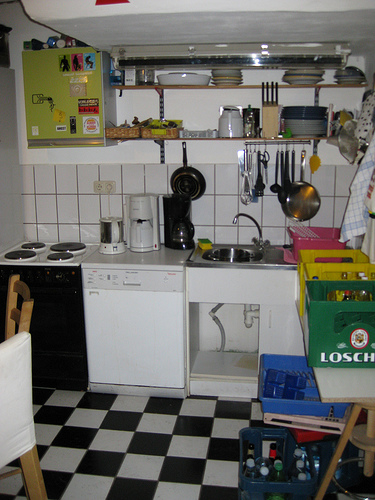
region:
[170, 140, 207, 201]
a black metal frying pan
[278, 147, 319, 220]
a silver metal pot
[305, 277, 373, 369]
a green plastic crate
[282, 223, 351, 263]
a pink dish rack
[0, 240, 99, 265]
a four burner stove top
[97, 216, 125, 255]
a white coffee pot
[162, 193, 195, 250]
a black coffee pot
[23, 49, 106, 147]
a green cabinet door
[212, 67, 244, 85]
a stack of bowls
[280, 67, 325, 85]
a stack of plates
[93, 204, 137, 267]
a coffee pot on the counter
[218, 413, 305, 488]
bottles in a crate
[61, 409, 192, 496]
a checker pattern on the floor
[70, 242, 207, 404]
a dishwasher in the kitchen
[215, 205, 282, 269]
a sink in the kitchen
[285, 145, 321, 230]
a pan hanging over a sink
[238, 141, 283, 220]
utensils hanging over a sink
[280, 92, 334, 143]
plates on the shelf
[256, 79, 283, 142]
a knife set on the shelf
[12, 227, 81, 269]
top of a stove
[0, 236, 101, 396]
A small black stove and oven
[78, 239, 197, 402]
A white dishwasher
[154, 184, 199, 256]
A black coffee maker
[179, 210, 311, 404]
A small kitchen sink and cabinet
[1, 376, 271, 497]
A black and white kitchen tile floor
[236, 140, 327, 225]
Hanging skillet and cooking utensils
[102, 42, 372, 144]
Shelves of dishware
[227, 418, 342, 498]
A crate of bottles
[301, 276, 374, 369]
Green crate that says LOSCH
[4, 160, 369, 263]
A white tiled back splash and a red dishpan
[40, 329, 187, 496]
the floor is white and black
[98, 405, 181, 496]
the floor is white and black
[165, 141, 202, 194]
a frying pan hanging on a wall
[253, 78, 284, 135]
a set of steak knives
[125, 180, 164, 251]
a white coffee pot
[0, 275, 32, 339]
a wooden chair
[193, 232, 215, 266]
a yellow and green sponge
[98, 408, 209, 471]
black and white checkard floor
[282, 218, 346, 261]
a pink tub on the counter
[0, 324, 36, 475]
a wooden chair with a white back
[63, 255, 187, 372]
a white dishwasher